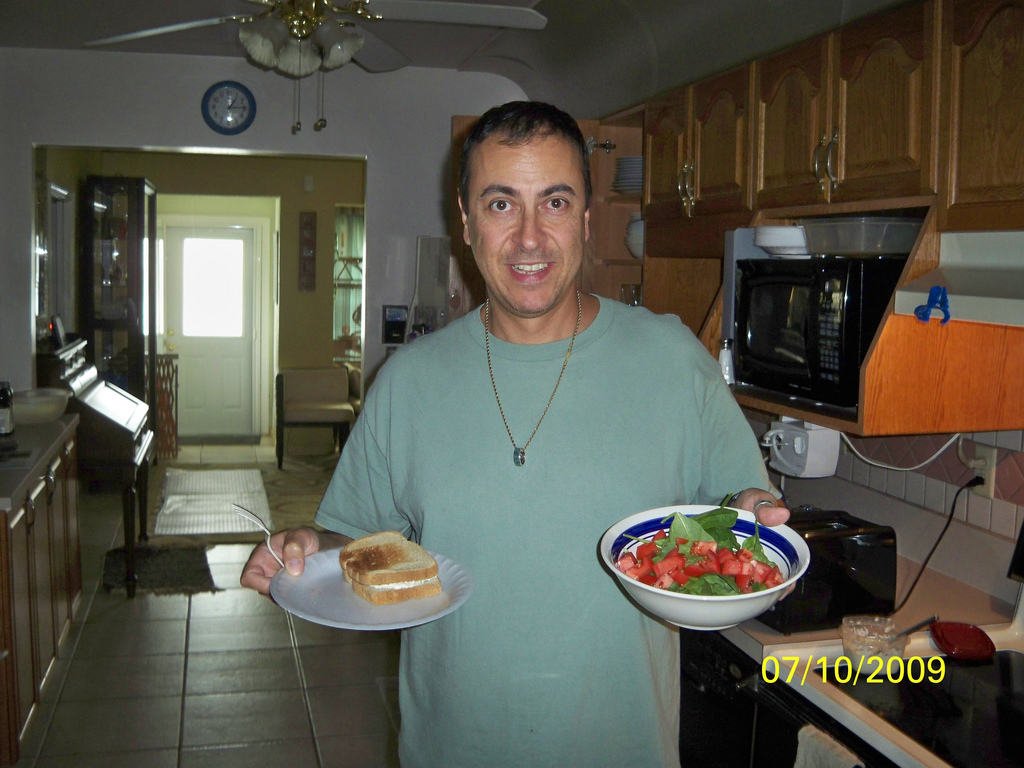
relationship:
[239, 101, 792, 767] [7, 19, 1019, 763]
man standing in kitchen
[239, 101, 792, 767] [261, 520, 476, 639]
man holding plate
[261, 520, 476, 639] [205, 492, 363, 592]
plate in hand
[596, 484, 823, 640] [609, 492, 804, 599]
bowl has stripe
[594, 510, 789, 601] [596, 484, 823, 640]
salad in bowl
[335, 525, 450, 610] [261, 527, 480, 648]
sandwich on plate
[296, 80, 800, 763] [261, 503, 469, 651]
man holding plate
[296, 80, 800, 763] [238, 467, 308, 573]
man holding utensil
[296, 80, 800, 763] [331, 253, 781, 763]
man wearing t-shirt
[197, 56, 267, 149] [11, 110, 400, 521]
clock over doorway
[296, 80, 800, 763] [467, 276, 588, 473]
man wearing necklace